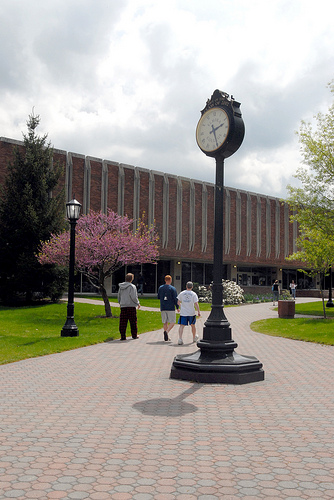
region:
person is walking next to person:
[114, 271, 140, 340]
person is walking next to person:
[157, 273, 178, 341]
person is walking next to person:
[177, 280, 203, 344]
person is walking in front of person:
[271, 279, 281, 305]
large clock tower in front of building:
[166, 88, 263, 377]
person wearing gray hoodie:
[116, 272, 139, 341]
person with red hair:
[153, 274, 178, 343]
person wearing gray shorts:
[155, 274, 176, 340]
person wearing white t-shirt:
[174, 279, 199, 348]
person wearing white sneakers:
[175, 280, 199, 345]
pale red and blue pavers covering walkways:
[1, 294, 327, 495]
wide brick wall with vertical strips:
[2, 136, 328, 270]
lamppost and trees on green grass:
[2, 104, 175, 352]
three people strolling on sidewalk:
[109, 268, 196, 341]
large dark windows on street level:
[63, 247, 328, 296]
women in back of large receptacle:
[259, 272, 298, 316]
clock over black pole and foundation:
[167, 84, 266, 383]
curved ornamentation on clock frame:
[190, 82, 239, 153]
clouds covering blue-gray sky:
[3, 0, 327, 202]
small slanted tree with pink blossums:
[35, 203, 161, 318]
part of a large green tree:
[284, 80, 333, 281]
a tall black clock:
[168, 88, 272, 384]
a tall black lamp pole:
[60, 197, 87, 338]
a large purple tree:
[34, 205, 163, 325]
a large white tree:
[199, 277, 244, 305]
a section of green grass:
[249, 313, 332, 346]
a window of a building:
[139, 257, 158, 289]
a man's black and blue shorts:
[177, 314, 197, 324]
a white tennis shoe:
[177, 338, 185, 345]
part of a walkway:
[225, 299, 270, 331]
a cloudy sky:
[21, 41, 278, 178]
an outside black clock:
[161, 87, 273, 395]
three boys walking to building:
[102, 256, 218, 370]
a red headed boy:
[154, 262, 203, 348]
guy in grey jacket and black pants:
[107, 254, 168, 367]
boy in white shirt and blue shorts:
[169, 273, 210, 355]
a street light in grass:
[36, 183, 120, 366]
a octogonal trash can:
[271, 284, 306, 321]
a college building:
[48, 132, 327, 309]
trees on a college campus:
[12, 105, 148, 342]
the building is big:
[1, 134, 333, 299]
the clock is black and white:
[169, 83, 266, 384]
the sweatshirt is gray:
[114, 280, 140, 306]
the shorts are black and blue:
[177, 314, 197, 324]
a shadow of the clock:
[130, 382, 203, 418]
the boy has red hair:
[162, 273, 174, 283]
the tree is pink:
[33, 205, 160, 316]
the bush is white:
[197, 276, 245, 303]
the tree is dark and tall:
[0, 106, 77, 306]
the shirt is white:
[175, 289, 198, 316]